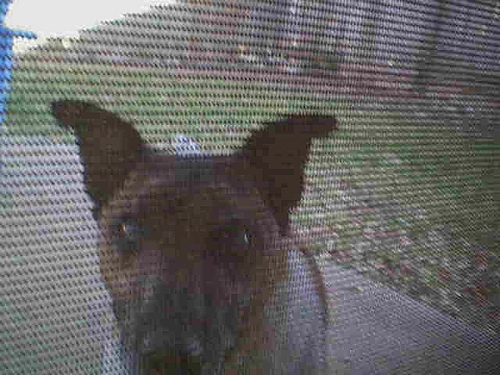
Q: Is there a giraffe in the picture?
A: No, there are no giraffes.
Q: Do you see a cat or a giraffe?
A: No, there are no giraffes or cats.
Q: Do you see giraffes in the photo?
A: No, there are no giraffes.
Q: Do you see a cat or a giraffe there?
A: No, there are no giraffes or cats.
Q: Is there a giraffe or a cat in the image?
A: No, there are no giraffes or cats.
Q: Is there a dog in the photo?
A: Yes, there is a dog.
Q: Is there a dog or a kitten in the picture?
A: Yes, there is a dog.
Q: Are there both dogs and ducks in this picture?
A: No, there is a dog but no ducks.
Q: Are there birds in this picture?
A: No, there are no birds.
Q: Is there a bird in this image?
A: No, there are no birds.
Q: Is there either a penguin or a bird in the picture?
A: No, there are no birds or penguins.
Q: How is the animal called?
A: The animal is a dog.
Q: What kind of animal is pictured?
A: The animal is a dog.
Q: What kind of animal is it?
A: The animal is a dog.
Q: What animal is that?
A: This is a dog.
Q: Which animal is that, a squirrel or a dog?
A: This is a dog.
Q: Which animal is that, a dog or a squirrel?
A: This is a dog.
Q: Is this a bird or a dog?
A: This is a dog.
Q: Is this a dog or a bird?
A: This is a dog.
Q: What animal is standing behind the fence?
A: The dog is standing behind the fence.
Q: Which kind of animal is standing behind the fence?
A: The animal is a dog.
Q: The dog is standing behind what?
A: The dog is standing behind the fence.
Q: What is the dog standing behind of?
A: The dog is standing behind the fence.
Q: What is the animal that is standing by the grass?
A: The animal is a dog.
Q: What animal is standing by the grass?
A: The animal is a dog.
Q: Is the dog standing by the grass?
A: Yes, the dog is standing by the grass.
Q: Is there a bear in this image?
A: No, there are no bears.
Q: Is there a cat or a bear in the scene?
A: No, there are no bears or cats.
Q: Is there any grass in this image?
A: Yes, there is grass.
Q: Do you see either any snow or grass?
A: Yes, there is grass.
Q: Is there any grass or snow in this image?
A: Yes, there is grass.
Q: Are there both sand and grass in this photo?
A: No, there is grass but no sand.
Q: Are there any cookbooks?
A: No, there are no cookbooks.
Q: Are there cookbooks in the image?
A: No, there are no cookbooks.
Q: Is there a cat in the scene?
A: No, there are no cats.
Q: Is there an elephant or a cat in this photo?
A: No, there are no cats or elephants.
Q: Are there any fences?
A: Yes, there is a fence.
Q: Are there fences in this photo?
A: Yes, there is a fence.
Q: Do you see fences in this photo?
A: Yes, there is a fence.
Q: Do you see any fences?
A: Yes, there is a fence.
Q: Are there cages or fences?
A: Yes, there is a fence.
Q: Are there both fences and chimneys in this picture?
A: No, there is a fence but no chimneys.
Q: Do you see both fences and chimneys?
A: No, there is a fence but no chimneys.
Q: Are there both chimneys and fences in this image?
A: No, there is a fence but no chimneys.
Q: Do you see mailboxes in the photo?
A: No, there are no mailboxes.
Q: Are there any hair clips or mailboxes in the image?
A: No, there are no mailboxes or hair clips.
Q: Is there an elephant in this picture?
A: No, there are no elephants.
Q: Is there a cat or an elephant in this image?
A: No, there are no elephants or cats.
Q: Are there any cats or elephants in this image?
A: No, there are no elephants or cats.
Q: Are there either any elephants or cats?
A: No, there are no elephants or cats.